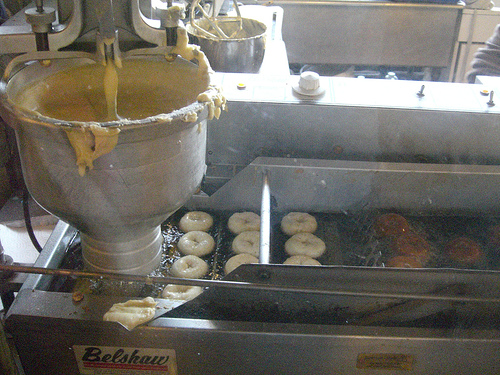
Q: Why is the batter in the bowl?
A: To make doughnuts.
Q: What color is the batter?
A: Yellow.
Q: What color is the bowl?
A: Silver.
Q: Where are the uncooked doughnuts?
A: Beside the bowl.